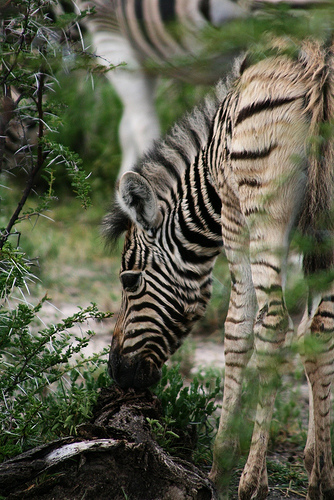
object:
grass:
[0, 382, 218, 499]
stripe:
[251, 258, 281, 275]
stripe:
[244, 205, 266, 217]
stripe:
[230, 137, 279, 161]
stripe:
[234, 95, 305, 127]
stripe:
[225, 362, 246, 368]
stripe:
[225, 333, 251, 341]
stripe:
[225, 316, 249, 324]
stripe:
[121, 328, 163, 349]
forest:
[0, 0, 334, 500]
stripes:
[123, 301, 188, 339]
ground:
[0, 195, 334, 500]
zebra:
[97, 43, 287, 487]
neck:
[160, 112, 222, 276]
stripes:
[145, 269, 208, 305]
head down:
[100, 170, 214, 389]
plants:
[0, 0, 224, 462]